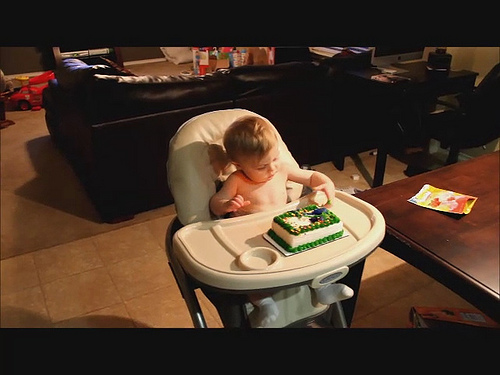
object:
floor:
[0, 160, 497, 327]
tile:
[36, 265, 126, 322]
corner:
[351, 172, 418, 245]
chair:
[167, 106, 351, 329]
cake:
[265, 203, 346, 253]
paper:
[406, 183, 478, 215]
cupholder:
[239, 247, 278, 269]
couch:
[39, 51, 401, 224]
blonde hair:
[224, 116, 277, 157]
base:
[425, 49, 453, 75]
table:
[348, 145, 500, 305]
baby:
[207, 112, 354, 324]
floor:
[0, 217, 180, 328]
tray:
[169, 180, 389, 297]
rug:
[0, 105, 98, 255]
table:
[346, 59, 481, 170]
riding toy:
[8, 70, 56, 111]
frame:
[172, 224, 230, 287]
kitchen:
[6, 46, 500, 325]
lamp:
[426, 48, 453, 72]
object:
[311, 191, 329, 205]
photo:
[0, 45, 497, 333]